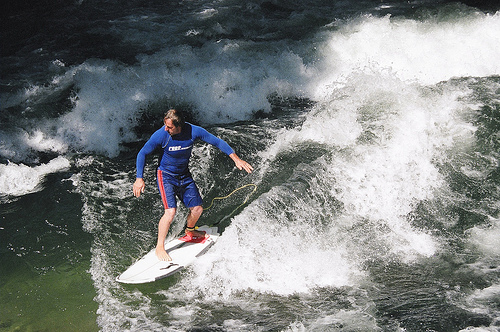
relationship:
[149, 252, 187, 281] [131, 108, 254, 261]
foot on man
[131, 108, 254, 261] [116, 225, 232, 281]
man riding surfboard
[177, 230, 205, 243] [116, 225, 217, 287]
red logo on surfboard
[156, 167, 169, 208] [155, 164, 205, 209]
red stripe on blue shorts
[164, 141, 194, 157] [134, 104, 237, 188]
white lettering on shirt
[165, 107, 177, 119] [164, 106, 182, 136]
hair on head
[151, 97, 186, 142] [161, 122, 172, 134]
face has nose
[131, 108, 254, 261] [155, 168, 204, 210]
man wearing blue shorts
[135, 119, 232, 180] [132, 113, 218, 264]
wetsuit man wearing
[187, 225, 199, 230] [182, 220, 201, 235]
band around mans ankle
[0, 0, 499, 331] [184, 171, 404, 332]
water man riding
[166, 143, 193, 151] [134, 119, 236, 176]
writing on mans shirt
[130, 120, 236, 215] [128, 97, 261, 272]
wetsuit on man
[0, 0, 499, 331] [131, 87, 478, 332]
water wave splashing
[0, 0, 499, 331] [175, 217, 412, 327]
water wave splashing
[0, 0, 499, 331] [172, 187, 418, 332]
water wave splashing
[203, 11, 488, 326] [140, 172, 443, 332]
water wave splashing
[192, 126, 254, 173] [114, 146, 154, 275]
arm reaching forward